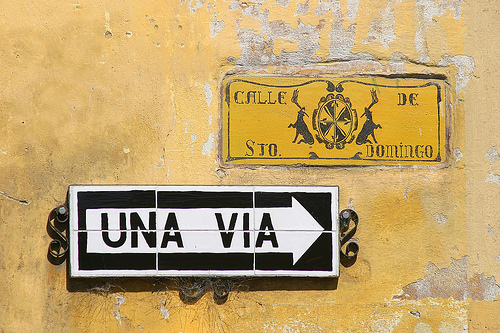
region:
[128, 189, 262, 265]
A black and white sign.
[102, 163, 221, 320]
A black and white sign.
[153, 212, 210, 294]
A black and white sign.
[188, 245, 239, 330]
A black and white sign.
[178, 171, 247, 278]
A black and white sign.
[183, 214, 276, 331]
A black and white sign.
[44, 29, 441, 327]
two signs on yellow building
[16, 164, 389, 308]
black street sign says una via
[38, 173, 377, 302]
one way street sign in spanish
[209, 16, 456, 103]
concrete cracking in photograph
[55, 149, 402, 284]
black street sign with white trim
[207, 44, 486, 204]
yellow sign with black writing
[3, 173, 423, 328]
metal embellishments on sides of sign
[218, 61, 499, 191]
yellow sign with black emblem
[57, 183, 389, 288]
black street sign with white arrow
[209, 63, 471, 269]
yellow sign above black and white sign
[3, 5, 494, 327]
the wall is yellow.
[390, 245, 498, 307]
the paint is peeling.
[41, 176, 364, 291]
the sign is black and white.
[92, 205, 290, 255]
the text is black.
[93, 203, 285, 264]
Text says UNA VIA.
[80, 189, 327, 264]
the arrow is white.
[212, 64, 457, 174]
the sign is yellow.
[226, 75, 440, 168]
the text on the sign is black.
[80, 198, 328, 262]
the arrow points right.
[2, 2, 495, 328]
the wall is painted.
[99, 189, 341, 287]
A black and white sign is visible.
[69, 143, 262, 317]
A black and white sign is visible.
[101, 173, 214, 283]
A black and white sign is visible.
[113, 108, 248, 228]
A black and white sign is visible.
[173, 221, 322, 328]
A black and white sign is visible.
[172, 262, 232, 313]
A black and white sign is visible.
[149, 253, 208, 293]
A black and white sign is visible.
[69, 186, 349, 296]
black and white sign on wall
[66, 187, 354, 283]
sign says una via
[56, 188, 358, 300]
sign has a white arrow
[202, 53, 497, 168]
yellow sign on wall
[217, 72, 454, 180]
sign has black writing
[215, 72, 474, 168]
sign says calle de sto. domingo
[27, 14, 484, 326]
wall is painted yellow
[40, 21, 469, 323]
wall has chipped paint and plaster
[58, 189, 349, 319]
sign is made from tile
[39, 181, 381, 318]
sign has wrought iron frame